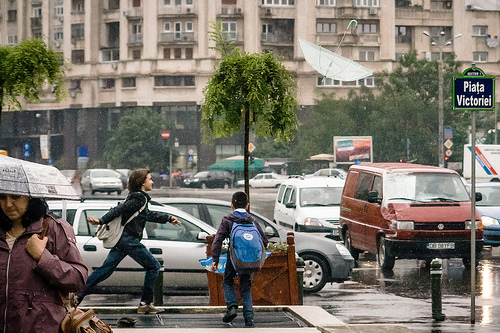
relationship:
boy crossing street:
[210, 191, 269, 328] [115, 271, 492, 330]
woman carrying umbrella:
[12, 159, 86, 331] [7, 162, 96, 209]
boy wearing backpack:
[210, 191, 269, 328] [230, 223, 262, 275]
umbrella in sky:
[290, 37, 373, 94] [226, 19, 499, 75]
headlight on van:
[383, 218, 422, 234] [349, 166, 490, 261]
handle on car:
[147, 240, 177, 259] [61, 208, 332, 284]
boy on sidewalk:
[210, 191, 269, 328] [99, 317, 284, 328]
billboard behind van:
[312, 124, 390, 168] [349, 166, 490, 261]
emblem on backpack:
[241, 230, 254, 244] [230, 223, 262, 275]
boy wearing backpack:
[185, 189, 283, 318] [230, 223, 262, 275]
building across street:
[33, 19, 350, 177] [115, 271, 492, 330]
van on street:
[349, 166, 490, 261] [115, 271, 492, 330]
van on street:
[258, 173, 333, 234] [115, 271, 492, 330]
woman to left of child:
[12, 159, 86, 331] [203, 191, 263, 327]